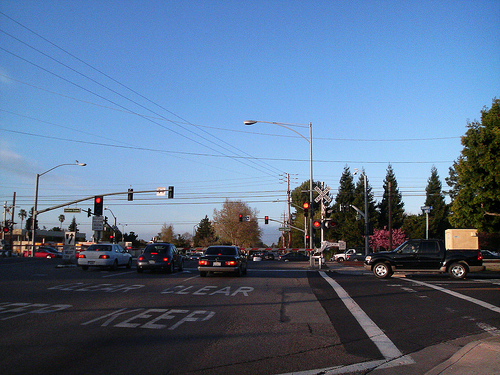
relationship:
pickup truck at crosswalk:
[365, 239, 485, 279] [316, 265, 407, 368]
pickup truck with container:
[365, 239, 485, 279] [445, 227, 479, 249]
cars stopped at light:
[25, 231, 252, 282] [77, 180, 198, 222]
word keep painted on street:
[101, 300, 229, 340] [6, 267, 476, 366]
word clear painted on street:
[165, 279, 263, 305] [6, 267, 476, 366]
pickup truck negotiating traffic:
[354, 234, 495, 286] [49, 230, 259, 286]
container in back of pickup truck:
[442, 221, 479, 256] [365, 239, 485, 279]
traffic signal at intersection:
[90, 191, 108, 220] [46, 237, 400, 373]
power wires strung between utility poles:
[166, 190, 288, 206] [25, 110, 327, 273]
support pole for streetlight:
[305, 118, 317, 281] [239, 106, 319, 153]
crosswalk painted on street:
[316, 265, 407, 368] [6, 261, 492, 368]